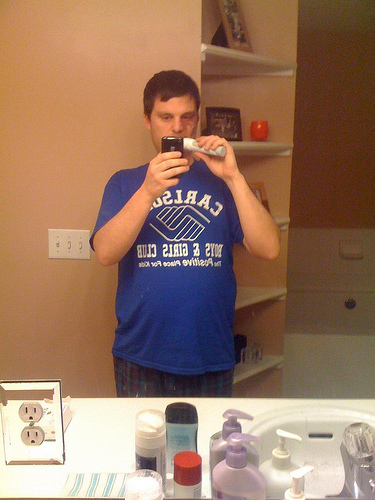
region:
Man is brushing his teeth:
[108, 60, 240, 204]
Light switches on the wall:
[42, 222, 95, 265]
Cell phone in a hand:
[139, 132, 193, 199]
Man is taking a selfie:
[122, 61, 217, 194]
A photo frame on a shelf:
[199, 7, 292, 68]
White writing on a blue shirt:
[88, 157, 250, 379]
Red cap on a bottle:
[169, 448, 206, 490]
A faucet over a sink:
[242, 404, 372, 498]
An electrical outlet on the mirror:
[1, 377, 68, 472]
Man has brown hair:
[136, 66, 203, 137]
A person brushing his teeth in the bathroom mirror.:
[77, 63, 286, 351]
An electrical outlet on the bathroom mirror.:
[1, 374, 75, 472]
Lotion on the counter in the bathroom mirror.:
[210, 408, 265, 497]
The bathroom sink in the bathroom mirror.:
[238, 405, 374, 498]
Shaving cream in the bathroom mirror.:
[167, 450, 210, 498]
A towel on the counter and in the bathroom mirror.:
[64, 466, 135, 499]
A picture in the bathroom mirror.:
[214, 2, 295, 86]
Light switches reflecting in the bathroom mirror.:
[36, 223, 99, 263]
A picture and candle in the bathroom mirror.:
[197, 92, 289, 153]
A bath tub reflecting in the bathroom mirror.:
[287, 224, 372, 395]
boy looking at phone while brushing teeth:
[132, 68, 240, 200]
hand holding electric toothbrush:
[181, 134, 231, 166]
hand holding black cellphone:
[151, 136, 191, 193]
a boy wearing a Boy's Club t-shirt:
[87, 71, 284, 377]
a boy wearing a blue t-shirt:
[88, 70, 300, 383]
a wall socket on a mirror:
[0, 380, 63, 466]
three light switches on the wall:
[45, 225, 95, 265]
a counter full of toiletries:
[81, 395, 316, 496]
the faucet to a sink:
[319, 413, 372, 492]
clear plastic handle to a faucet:
[338, 420, 372, 457]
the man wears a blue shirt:
[94, 162, 245, 368]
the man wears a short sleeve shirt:
[97, 156, 241, 367]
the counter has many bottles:
[122, 409, 304, 496]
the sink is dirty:
[240, 413, 368, 499]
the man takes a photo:
[159, 137, 185, 164]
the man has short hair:
[141, 71, 202, 122]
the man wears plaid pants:
[110, 350, 230, 397]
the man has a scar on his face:
[182, 110, 196, 131]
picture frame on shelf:
[201, 106, 244, 141]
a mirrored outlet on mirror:
[0, 382, 65, 464]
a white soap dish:
[336, 232, 369, 257]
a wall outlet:
[0, 374, 65, 467]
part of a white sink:
[248, 404, 373, 488]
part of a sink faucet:
[331, 430, 374, 498]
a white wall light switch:
[44, 228, 91, 260]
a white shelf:
[196, 41, 300, 86]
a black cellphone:
[159, 136, 186, 182]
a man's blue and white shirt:
[87, 158, 250, 377]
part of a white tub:
[285, 331, 373, 401]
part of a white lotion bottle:
[255, 426, 306, 496]